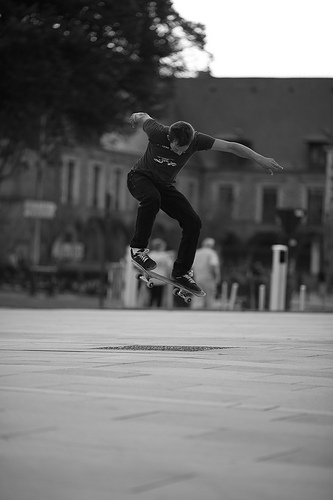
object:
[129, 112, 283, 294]
guy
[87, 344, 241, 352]
grate pavement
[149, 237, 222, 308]
two people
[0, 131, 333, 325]
park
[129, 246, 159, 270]
foot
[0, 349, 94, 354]
shadow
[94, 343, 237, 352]
skateboarder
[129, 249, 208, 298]
board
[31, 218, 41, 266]
pole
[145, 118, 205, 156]
suitcase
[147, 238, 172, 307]
woman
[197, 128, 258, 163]
arms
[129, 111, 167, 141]
right arm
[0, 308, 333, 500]
ground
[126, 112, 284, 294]
skater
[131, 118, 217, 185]
t-shirt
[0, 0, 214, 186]
trees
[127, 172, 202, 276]
pants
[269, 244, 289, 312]
container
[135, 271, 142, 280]
wheel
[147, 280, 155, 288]
wheel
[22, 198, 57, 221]
sign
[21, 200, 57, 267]
sign whole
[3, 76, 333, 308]
building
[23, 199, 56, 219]
signboard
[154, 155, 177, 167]
logo